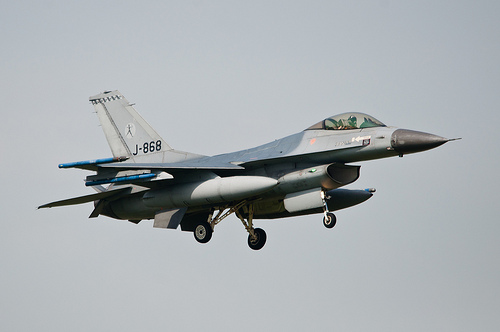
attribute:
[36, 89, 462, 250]
airplane — gray color, grey, jet, gray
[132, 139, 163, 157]
identification — black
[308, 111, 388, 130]
cockpit — clear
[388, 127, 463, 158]
nose — dark grey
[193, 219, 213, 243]
wheel — black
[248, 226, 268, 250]
wheel — black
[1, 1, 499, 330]
sky — gray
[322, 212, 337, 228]
wheel — black, small